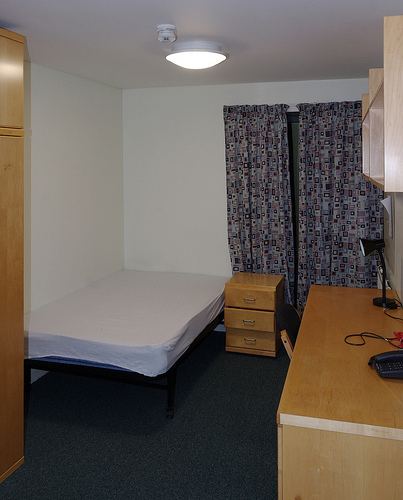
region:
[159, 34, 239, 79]
light in the ceiling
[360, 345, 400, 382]
phone on a desk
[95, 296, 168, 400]
bed in a room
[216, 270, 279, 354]
table near a bed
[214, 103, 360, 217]
curtain on a window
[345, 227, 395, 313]
lamp on a desk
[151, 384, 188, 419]
leg on a bed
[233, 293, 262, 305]
handle on a desk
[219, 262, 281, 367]
three drawer chest next to bed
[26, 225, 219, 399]
bed against the wall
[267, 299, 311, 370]
chair sitting at the desk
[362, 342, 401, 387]
telephone on the desk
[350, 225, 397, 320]
lamp sitting on the desk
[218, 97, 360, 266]
patterned curtains on the window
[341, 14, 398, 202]
wall shelf above the desk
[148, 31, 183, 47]
smoke alarm next to the ceiling light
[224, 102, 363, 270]
curtain on the window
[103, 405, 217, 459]
the carpet is dark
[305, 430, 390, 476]
side of the desk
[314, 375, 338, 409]
the desk is wood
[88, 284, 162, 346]
sheet on the bed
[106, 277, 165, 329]
the sheets are white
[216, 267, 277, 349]
the cabinet is wood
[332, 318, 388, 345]
cord on the desk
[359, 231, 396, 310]
light on the desk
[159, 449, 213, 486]
the carpet is blue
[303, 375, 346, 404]
the desk is brown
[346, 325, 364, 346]
a black cord on the desk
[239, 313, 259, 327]
handle on the dresser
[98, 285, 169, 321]
white sheets on the bed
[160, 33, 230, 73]
A light is on.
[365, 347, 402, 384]
A phone can be seen on a desk.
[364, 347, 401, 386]
The color of a phone is black.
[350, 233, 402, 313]
A small lamp is sitting on a desk.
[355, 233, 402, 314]
The color of a small lamp is black.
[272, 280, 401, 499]
The color of a desk is brown.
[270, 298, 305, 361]
a chair is parked under a desk.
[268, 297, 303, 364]
The colors of a chair are black and brown.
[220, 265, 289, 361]
Drawers are open on a nightstand.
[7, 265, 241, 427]
A bed is in a corner.